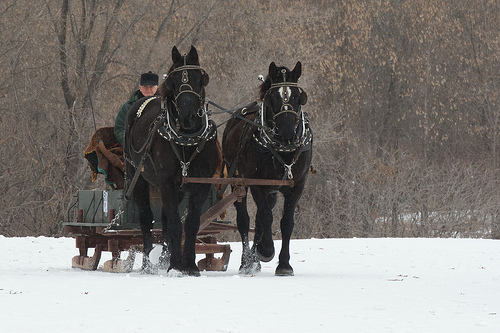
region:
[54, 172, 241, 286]
sleigh is green and brown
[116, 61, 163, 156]
man in green and black hat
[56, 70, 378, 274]
Horses pulling a sled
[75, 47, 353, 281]
Two horses pulling a sled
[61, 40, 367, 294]
Two black horses pulling a sled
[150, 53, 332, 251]
Two black horses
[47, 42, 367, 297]
A man with horses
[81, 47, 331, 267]
A man with two horses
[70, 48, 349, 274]
A man with two black horses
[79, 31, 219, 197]
A man with a horse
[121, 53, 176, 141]
A man wearing a cap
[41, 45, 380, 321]
Horses pulling a sled in the snow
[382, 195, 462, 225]
small patch of snow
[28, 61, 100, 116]
black trunks on bare tree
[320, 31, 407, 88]
yellow leaves on tree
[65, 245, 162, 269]
bottom of vehicle covered with snow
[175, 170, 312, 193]
brown bars around horse's neck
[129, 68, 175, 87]
black cap on man's head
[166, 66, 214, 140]
reins around horse's neck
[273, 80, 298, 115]
white spot on horses head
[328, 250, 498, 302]
spots in the white snow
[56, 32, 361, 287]
horses being driven by man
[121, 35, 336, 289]
black horses pulling the sled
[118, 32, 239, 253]
black horse pulling wagon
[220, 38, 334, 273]
black horse pulling wagon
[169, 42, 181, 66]
ear belongs to horse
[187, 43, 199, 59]
ear belongs to horse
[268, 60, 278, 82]
ear belongs to horse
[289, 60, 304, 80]
ear belongs to horse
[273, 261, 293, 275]
hoof belongs to horse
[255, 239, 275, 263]
hoof belongs to horse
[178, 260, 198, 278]
hoof belongs to horse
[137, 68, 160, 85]
hat worn by human